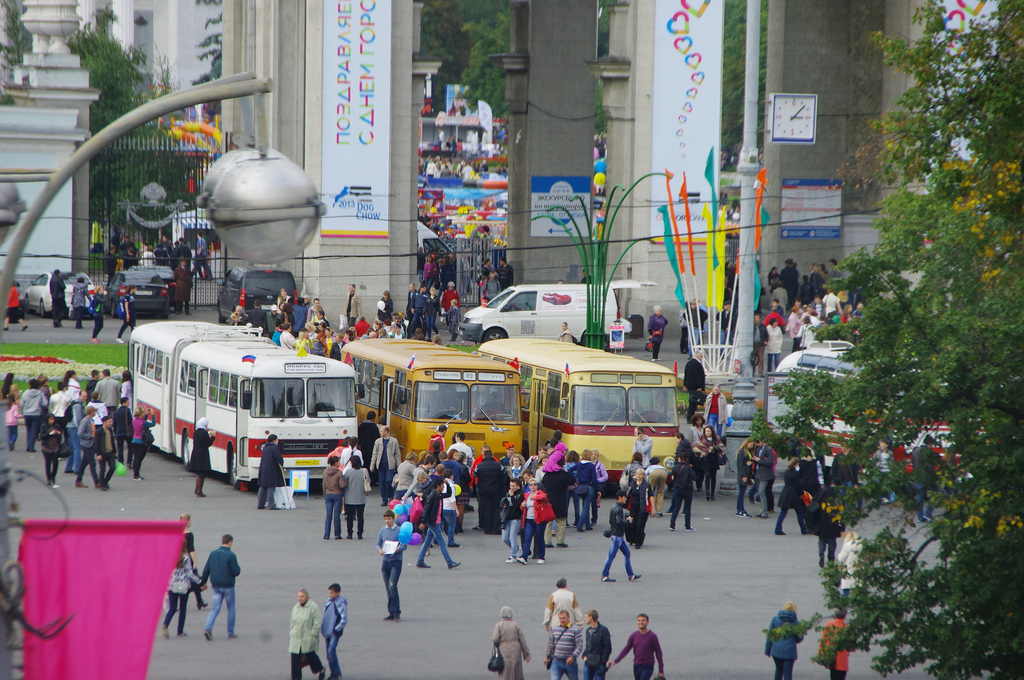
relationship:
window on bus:
[310, 375, 355, 413] [124, 321, 360, 476]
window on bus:
[247, 377, 306, 417] [124, 321, 360, 476]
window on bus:
[414, 381, 468, 423] [336, 337, 526, 456]